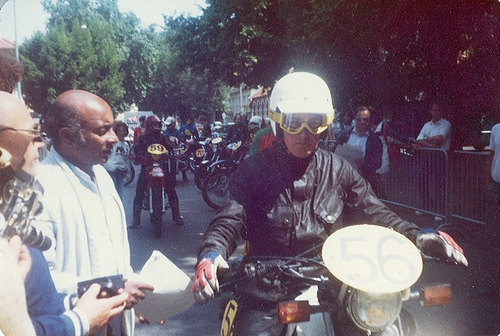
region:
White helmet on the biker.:
[250, 36, 365, 136]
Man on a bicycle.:
[173, 69, 352, 318]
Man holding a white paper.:
[123, 234, 200, 334]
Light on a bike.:
[320, 266, 400, 328]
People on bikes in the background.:
[126, 102, 252, 231]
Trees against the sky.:
[36, 0, 251, 135]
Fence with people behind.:
[380, 117, 497, 227]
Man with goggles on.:
[272, 108, 345, 164]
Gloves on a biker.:
[179, 245, 239, 324]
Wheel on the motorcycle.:
[146, 186, 171, 242]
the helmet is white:
[256, 58, 347, 148]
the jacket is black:
[222, 149, 372, 247]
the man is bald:
[36, 75, 138, 183]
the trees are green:
[76, 17, 186, 98]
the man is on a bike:
[127, 98, 201, 243]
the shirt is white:
[40, 151, 135, 268]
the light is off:
[338, 274, 403, 334]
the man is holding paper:
[110, 241, 206, 328]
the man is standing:
[388, 80, 459, 236]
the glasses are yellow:
[259, 94, 351, 149]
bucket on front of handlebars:
[295, 209, 436, 334]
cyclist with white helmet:
[193, 70, 461, 335]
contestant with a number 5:
[206, 292, 244, 334]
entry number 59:
[137, 135, 172, 160]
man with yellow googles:
[260, 61, 338, 166]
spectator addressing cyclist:
[36, 89, 191, 334]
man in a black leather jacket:
[182, 69, 464, 334]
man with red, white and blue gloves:
[188, 219, 480, 301]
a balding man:
[39, 83, 123, 173]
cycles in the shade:
[129, 91, 261, 226]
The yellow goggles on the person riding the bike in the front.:
[271, 108, 344, 134]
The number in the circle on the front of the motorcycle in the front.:
[325, 225, 440, 292]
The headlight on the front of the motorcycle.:
[348, 290, 400, 332]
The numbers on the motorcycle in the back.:
[146, 141, 168, 154]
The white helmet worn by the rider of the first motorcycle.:
[268, 72, 333, 117]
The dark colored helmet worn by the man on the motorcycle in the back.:
[142, 111, 168, 131]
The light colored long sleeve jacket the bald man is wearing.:
[47, 158, 129, 285]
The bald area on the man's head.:
[54, 91, 113, 118]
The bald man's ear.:
[57, 127, 76, 148]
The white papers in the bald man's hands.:
[130, 245, 193, 320]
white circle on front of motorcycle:
[323, 223, 423, 293]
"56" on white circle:
[339, 233, 412, 283]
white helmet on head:
[265, 70, 334, 160]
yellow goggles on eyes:
[268, 108, 334, 132]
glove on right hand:
[193, 248, 230, 296]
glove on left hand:
[416, 226, 466, 268]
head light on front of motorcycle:
[344, 283, 408, 330]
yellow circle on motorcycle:
[147, 144, 164, 156]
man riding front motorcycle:
[200, 71, 459, 329]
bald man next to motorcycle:
[41, 83, 158, 334]